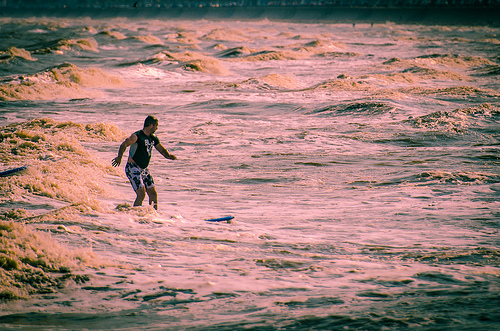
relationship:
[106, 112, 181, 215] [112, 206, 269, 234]
man stands on surfboard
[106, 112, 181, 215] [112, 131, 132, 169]
man extends arm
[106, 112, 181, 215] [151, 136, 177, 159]
man extends arm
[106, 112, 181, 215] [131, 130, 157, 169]
man with tank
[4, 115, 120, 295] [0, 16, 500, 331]
weeds on ocean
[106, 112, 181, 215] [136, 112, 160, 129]
man has hair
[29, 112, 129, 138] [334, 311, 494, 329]
waves speeding toward shore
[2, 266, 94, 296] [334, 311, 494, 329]
waves speeding toward shore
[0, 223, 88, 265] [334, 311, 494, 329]
waves speeding toward shore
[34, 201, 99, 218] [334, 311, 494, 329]
waves speeding toward shore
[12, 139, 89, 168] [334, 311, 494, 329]
waves speeding toward shore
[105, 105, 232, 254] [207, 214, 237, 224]
surf board has tip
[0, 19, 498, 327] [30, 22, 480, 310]
water with hues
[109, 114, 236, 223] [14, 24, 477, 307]
man surfing on water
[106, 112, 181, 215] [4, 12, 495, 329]
man surfing in ocean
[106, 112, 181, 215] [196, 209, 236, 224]
man standing on surfboard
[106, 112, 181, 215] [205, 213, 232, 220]
man standing on surfboard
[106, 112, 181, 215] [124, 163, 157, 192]
man wearing shorts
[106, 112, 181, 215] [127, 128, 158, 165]
man wearing shirt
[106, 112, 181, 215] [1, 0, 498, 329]
man surfing in waves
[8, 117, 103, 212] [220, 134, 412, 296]
foam on top of water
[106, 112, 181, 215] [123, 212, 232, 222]
man on surfboard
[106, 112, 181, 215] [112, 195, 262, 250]
man on surfboard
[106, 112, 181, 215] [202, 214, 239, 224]
man on surfboard tip